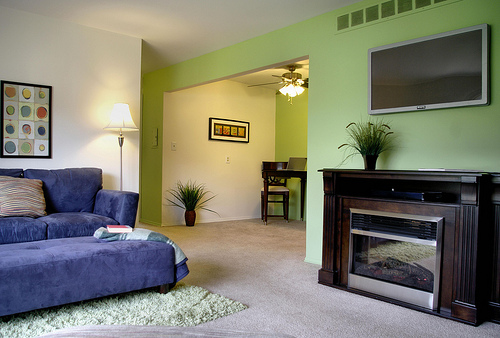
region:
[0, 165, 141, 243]
a large purple sofa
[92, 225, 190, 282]
a green and white blanket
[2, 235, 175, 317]
a large purple ottoman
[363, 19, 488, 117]
A television on the wall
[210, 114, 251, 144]
a picture on the wall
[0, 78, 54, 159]
a picture on the wall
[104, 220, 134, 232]
a book on a blanket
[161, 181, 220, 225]
a potted plant on the floor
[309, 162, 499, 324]
an electric fireplace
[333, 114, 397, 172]
a potted plant on a fireplace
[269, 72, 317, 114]
white lights on fan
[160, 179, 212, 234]
green plant in pot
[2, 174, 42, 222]
brown pillow on sofa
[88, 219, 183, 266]
green blanket near sofa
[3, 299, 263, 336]
green and shaggy rug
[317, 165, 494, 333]
brown fireplace in room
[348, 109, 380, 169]
small plant on fireplace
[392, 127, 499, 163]
green wall in room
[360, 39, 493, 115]
tv on green wall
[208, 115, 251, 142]
framed art on the wall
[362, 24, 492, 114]
a flat screen TV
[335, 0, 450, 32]
the vent is painted green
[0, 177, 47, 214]
a pillow on the couch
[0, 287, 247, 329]
a shag area rug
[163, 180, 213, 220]
a house plant in the room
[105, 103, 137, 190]
the lamp is on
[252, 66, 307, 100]
a ceiling fan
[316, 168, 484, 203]
wood fireplace mantle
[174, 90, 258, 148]
a black picture frame on the wall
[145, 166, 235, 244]
a plant on the floor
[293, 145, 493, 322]
a brown fire place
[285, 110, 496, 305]
a plant on a fire place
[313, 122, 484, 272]
a plant on a wooden fire place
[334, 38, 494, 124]
a tv on the wall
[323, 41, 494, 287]
a tv above a fire plce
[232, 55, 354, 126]
a fan on the ceiling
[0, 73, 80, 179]
a picture frame on the wall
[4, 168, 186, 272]
a blue couch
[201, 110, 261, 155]
image on the wall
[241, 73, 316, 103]
fan with light on it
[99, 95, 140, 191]
lamp against the wall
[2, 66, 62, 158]
image on the wall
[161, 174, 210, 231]
plant on the ground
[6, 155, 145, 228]
couch against the wall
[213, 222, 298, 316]
carpet on the floor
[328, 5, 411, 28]
vents on the wall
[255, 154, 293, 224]
chair near the plants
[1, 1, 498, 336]
Clean and tidy family room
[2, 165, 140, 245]
Pillow on purple couch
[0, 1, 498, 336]
Room has carpet flooring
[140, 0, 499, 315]
wall is painted green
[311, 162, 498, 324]
fireplace on green wall